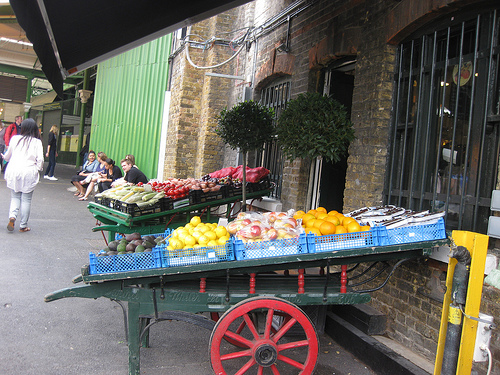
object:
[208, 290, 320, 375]
wheel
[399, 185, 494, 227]
bars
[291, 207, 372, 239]
oranges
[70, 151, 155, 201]
people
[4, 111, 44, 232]
girl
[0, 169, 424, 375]
street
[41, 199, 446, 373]
fruit cart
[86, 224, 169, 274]
basket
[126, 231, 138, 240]
avocado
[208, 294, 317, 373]
wheel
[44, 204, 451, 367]
cart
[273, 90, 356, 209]
plant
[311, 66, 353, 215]
doorway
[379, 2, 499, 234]
bars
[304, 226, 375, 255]
crate